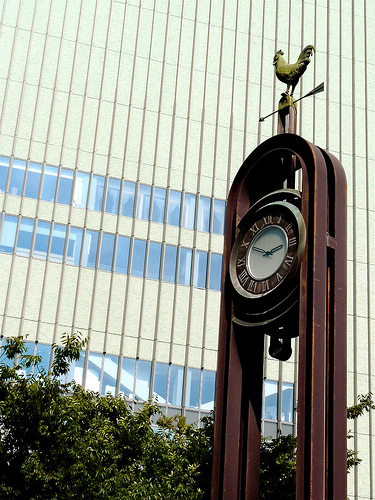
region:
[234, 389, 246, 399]
part of a window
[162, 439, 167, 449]
part of a twig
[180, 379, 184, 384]
part of a window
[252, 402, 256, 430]
part of a clock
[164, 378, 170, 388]
edge of a window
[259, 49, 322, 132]
rooster weather vane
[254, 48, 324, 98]
rusted rooster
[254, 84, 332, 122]
rusted arrow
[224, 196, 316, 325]
clock face has roman numeral numbers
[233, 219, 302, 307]
time shown on clock is 2:10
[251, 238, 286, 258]
hands of clock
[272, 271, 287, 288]
roman numeral for the number five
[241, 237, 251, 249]
roman numeral for the number ten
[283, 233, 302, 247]
roman numeral for the number three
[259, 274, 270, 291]
roman numeral for the number six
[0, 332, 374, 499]
green tree in front of the building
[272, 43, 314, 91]
metal molded chicken replica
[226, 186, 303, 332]
a big clock with white interior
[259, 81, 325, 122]
a molded iron arrow replica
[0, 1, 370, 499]
a big glass tower buiding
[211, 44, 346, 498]
big brown clock with metal pillars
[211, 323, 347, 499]
metal brown pillars for clock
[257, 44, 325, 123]
molded metal chicken windvane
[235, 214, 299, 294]
clock reading ten minutes to three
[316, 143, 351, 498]
carved out place in the right side of the clock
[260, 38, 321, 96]
chicken on top of a tower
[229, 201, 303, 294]
clock on a tower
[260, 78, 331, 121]
arrow on a tower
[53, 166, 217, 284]
glass windows on a building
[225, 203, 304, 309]
clock on top of a tower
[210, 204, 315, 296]
clock on top of a tower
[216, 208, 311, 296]
clock on top of a tower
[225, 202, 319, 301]
clock on top of a tower